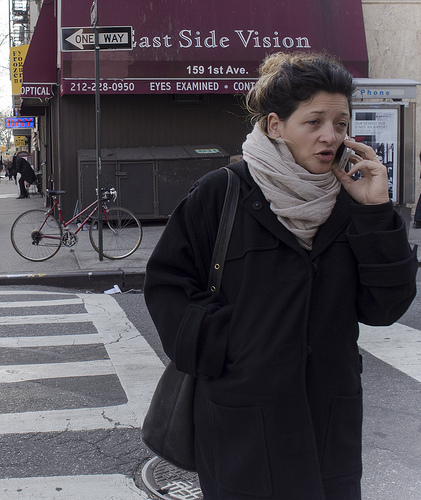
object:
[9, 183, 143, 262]
bike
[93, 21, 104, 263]
pole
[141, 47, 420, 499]
woman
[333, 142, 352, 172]
cell phone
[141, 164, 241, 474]
purse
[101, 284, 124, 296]
trash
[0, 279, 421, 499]
street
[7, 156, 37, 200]
man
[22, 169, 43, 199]
bench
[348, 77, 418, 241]
phone booth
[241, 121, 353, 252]
scarf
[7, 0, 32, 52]
fire escape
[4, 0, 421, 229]
building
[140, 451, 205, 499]
man hole cover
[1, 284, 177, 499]
pedestrian crossing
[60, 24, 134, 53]
one way street sign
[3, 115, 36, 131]
sign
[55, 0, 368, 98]
awning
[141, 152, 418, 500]
coat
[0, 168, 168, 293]
sidewalk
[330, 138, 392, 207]
hand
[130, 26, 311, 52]
east side vision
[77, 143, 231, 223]
garbage bin